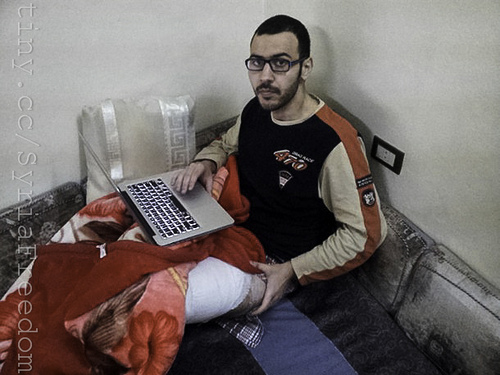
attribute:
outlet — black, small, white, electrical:
[367, 134, 403, 176]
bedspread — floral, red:
[0, 153, 266, 373]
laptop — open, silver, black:
[78, 131, 236, 248]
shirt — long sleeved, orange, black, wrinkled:
[192, 93, 389, 286]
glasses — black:
[245, 54, 310, 74]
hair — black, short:
[248, 14, 311, 64]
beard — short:
[251, 74, 305, 111]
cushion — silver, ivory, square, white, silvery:
[86, 92, 196, 204]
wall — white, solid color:
[1, 1, 264, 210]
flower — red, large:
[126, 309, 185, 375]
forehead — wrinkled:
[249, 33, 294, 58]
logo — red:
[273, 147, 308, 173]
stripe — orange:
[302, 103, 379, 294]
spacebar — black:
[170, 196, 186, 214]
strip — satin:
[101, 99, 123, 188]